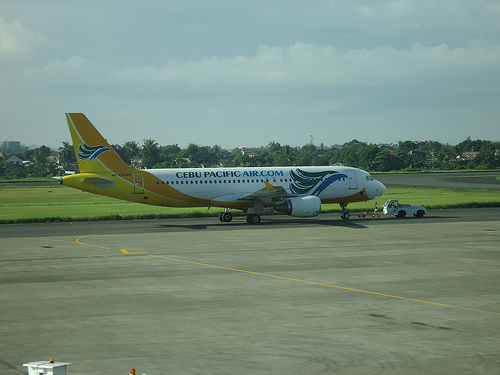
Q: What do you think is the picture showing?
A: It is showing a pavement.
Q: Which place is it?
A: It is a pavement.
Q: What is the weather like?
A: It is cloudy.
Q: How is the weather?
A: It is cloudy.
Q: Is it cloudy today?
A: Yes, it is cloudy.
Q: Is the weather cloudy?
A: Yes, it is cloudy.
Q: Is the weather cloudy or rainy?
A: It is cloudy.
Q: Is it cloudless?
A: No, it is cloudy.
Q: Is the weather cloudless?
A: No, it is cloudy.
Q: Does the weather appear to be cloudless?
A: No, it is cloudy.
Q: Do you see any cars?
A: No, there are no cars.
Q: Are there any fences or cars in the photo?
A: No, there are no cars or fences.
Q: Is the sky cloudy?
A: Yes, the sky is cloudy.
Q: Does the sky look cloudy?
A: Yes, the sky is cloudy.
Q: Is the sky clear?
A: No, the sky is cloudy.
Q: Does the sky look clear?
A: No, the sky is cloudy.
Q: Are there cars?
A: No, there are no cars.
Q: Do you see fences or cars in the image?
A: No, there are no cars or fences.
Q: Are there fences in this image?
A: No, there are no fences.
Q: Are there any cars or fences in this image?
A: No, there are no fences or cars.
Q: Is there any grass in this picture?
A: Yes, there is grass.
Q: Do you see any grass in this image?
A: Yes, there is grass.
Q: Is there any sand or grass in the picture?
A: Yes, there is grass.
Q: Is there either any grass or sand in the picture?
A: Yes, there is grass.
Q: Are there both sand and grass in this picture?
A: No, there is grass but no sand.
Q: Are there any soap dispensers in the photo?
A: No, there are no soap dispensers.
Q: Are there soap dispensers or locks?
A: No, there are no soap dispensers or locks.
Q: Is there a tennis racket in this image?
A: No, there are no rackets.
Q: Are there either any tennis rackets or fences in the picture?
A: No, there are no tennis rackets or fences.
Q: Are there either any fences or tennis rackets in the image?
A: No, there are no tennis rackets or fences.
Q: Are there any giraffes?
A: No, there are no giraffes.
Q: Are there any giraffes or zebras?
A: No, there are no giraffes or zebras.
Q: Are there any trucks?
A: Yes, there is a truck.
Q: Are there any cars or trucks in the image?
A: Yes, there is a truck.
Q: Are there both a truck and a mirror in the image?
A: No, there is a truck but no mirrors.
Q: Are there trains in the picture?
A: No, there are no trains.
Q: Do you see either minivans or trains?
A: No, there are no trains or minivans.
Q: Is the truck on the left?
A: No, the truck is on the right of the image.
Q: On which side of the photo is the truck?
A: The truck is on the right of the image.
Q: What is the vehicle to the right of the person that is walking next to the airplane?
A: The vehicle is a truck.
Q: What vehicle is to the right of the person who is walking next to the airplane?
A: The vehicle is a truck.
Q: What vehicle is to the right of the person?
A: The vehicle is a truck.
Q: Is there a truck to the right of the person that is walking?
A: Yes, there is a truck to the right of the person.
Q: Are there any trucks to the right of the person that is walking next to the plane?
A: Yes, there is a truck to the right of the person.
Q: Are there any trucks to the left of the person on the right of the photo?
A: No, the truck is to the right of the person.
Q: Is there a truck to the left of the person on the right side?
A: No, the truck is to the right of the person.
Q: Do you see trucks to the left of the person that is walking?
A: No, the truck is to the right of the person.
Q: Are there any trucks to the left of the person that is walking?
A: No, the truck is to the right of the person.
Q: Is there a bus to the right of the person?
A: No, there is a truck to the right of the person.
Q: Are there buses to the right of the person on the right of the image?
A: No, there is a truck to the right of the person.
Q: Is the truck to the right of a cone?
A: No, the truck is to the right of a person.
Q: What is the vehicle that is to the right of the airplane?
A: The vehicle is a truck.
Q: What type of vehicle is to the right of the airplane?
A: The vehicle is a truck.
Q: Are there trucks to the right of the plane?
A: Yes, there is a truck to the right of the plane.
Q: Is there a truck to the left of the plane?
A: No, the truck is to the right of the plane.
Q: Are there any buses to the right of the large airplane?
A: No, there is a truck to the right of the plane.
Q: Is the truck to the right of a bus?
A: No, the truck is to the right of the airplane.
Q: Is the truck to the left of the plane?
A: No, the truck is to the right of the plane.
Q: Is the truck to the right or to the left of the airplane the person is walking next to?
A: The truck is to the right of the plane.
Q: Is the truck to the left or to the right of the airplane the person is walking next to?
A: The truck is to the right of the plane.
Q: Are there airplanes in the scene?
A: Yes, there is an airplane.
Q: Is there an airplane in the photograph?
A: Yes, there is an airplane.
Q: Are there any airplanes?
A: Yes, there is an airplane.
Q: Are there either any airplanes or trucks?
A: Yes, there is an airplane.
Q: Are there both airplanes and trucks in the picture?
A: Yes, there are both an airplane and a truck.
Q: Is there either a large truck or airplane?
A: Yes, there is a large airplane.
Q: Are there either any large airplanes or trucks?
A: Yes, there is a large airplane.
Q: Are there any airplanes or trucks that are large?
A: Yes, the airplane is large.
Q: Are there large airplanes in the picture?
A: Yes, there is a large airplane.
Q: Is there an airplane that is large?
A: Yes, there is an airplane that is large.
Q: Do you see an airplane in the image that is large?
A: Yes, there is an airplane that is large.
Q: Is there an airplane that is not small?
A: Yes, there is a large airplane.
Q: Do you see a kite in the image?
A: No, there are no kites.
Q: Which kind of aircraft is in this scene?
A: The aircraft is an airplane.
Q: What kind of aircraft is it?
A: The aircraft is an airplane.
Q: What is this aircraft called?
A: This is an airplane.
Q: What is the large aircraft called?
A: The aircraft is an airplane.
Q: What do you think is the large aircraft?
A: The aircraft is an airplane.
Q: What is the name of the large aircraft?
A: The aircraft is an airplane.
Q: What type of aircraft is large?
A: The aircraft is an airplane.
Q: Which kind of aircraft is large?
A: The aircraft is an airplane.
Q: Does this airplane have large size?
A: Yes, the airplane is large.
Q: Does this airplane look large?
A: Yes, the airplane is large.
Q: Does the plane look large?
A: Yes, the plane is large.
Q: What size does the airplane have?
A: The airplane has large size.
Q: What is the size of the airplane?
A: The airplane is large.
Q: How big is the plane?
A: The plane is large.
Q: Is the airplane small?
A: No, the airplane is large.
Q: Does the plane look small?
A: No, the plane is large.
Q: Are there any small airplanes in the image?
A: No, there is an airplane but it is large.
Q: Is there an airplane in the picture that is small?
A: No, there is an airplane but it is large.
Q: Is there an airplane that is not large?
A: No, there is an airplane but it is large.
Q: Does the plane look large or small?
A: The plane is large.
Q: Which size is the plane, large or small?
A: The plane is large.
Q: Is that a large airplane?
A: Yes, that is a large airplane.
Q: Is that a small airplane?
A: No, that is a large airplane.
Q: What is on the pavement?
A: The airplane is on the pavement.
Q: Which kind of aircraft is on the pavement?
A: The aircraft is an airplane.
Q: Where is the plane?
A: The plane is on the pavement.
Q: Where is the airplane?
A: The plane is on the pavement.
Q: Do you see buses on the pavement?
A: No, there is an airplane on the pavement.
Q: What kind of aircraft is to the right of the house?
A: The aircraft is an airplane.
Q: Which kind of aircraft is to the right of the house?
A: The aircraft is an airplane.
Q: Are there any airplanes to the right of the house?
A: Yes, there is an airplane to the right of the house.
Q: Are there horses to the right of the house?
A: No, there is an airplane to the right of the house.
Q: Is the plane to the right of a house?
A: Yes, the plane is to the right of a house.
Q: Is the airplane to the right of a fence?
A: No, the airplane is to the right of a house.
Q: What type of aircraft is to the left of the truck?
A: The aircraft is an airplane.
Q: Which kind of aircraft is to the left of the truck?
A: The aircraft is an airplane.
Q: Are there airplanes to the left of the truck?
A: Yes, there is an airplane to the left of the truck.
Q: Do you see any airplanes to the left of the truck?
A: Yes, there is an airplane to the left of the truck.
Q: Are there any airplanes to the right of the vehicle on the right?
A: No, the airplane is to the left of the truck.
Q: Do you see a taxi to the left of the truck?
A: No, there is an airplane to the left of the truck.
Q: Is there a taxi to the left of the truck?
A: No, there is an airplane to the left of the truck.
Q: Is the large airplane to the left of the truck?
A: Yes, the airplane is to the left of the truck.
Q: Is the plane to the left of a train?
A: No, the plane is to the left of the truck.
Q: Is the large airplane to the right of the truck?
A: No, the airplane is to the left of the truck.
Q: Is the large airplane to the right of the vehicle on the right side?
A: No, the airplane is to the left of the truck.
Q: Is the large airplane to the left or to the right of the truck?
A: The airplane is to the left of the truck.